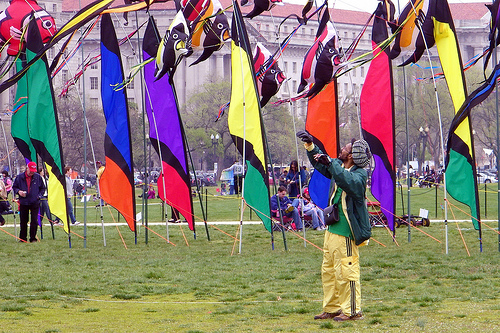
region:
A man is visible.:
[251, 107, 391, 329]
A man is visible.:
[250, 121, 342, 278]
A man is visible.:
[302, 140, 409, 314]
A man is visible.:
[221, 14, 381, 249]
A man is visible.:
[247, 91, 372, 306]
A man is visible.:
[298, 137, 365, 274]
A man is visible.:
[310, 127, 371, 282]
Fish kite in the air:
[6, 2, 57, 51]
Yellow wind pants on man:
[308, 235, 381, 320]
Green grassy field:
[86, 255, 211, 282]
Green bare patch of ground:
[90, 302, 171, 328]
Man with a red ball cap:
[13, 157, 55, 243]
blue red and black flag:
[101, 135, 146, 220]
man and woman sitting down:
[269, 187, 321, 225]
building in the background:
[249, 2, 400, 134]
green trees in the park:
[190, 86, 231, 175]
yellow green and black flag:
[426, 17, 490, 247]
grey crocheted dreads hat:
[350, 138, 372, 170]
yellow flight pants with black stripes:
[319, 229, 363, 316]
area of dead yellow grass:
[0, 291, 221, 331]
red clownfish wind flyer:
[0, 0, 59, 58]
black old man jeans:
[17, 201, 40, 242]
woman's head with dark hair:
[288, 161, 298, 174]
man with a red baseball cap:
[25, 160, 37, 173]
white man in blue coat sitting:
[270, 184, 304, 232]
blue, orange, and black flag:
[97, 11, 137, 233]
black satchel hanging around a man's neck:
[321, 203, 339, 226]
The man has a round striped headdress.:
[287, 124, 412, 323]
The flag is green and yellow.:
[0, 1, 81, 259]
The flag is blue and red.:
[89, 3, 141, 288]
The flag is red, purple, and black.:
[129, 11, 206, 251]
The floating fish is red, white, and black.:
[4, 1, 74, 70]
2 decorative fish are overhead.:
[143, 1, 243, 93]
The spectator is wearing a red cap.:
[0, 143, 77, 268]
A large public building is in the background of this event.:
[5, 1, 497, 201]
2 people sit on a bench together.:
[249, 170, 335, 240]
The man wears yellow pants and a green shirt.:
[294, 119, 383, 331]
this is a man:
[292, 131, 390, 326]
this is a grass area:
[146, 257, 236, 316]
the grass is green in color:
[136, 250, 185, 285]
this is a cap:
[27, 157, 37, 174]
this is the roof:
[457, 2, 472, 17]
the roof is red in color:
[331, 5, 343, 15]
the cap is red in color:
[26, 162, 33, 164]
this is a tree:
[191, 70, 221, 167]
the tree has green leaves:
[190, 105, 205, 140]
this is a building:
[258, 11, 303, 46]